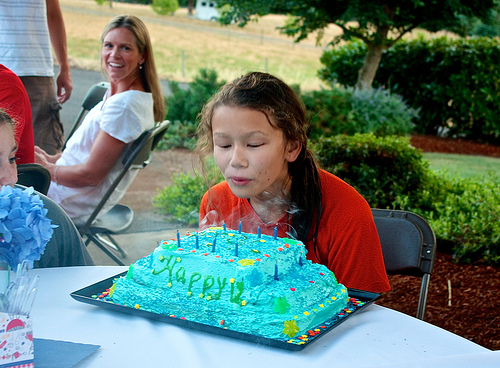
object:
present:
[0, 302, 41, 365]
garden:
[40, 0, 500, 351]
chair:
[355, 207, 435, 319]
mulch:
[380, 253, 499, 350]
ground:
[41, 110, 499, 348]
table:
[0, 264, 499, 368]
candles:
[236, 219, 243, 233]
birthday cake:
[108, 221, 350, 337]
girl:
[194, 67, 394, 300]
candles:
[222, 224, 227, 231]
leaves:
[312, 35, 325, 48]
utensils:
[0, 262, 40, 322]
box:
[0, 312, 38, 368]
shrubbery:
[314, 24, 497, 144]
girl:
[1, 109, 97, 271]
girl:
[21, 14, 163, 228]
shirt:
[46, 88, 153, 225]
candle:
[176, 231, 183, 247]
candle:
[193, 230, 200, 247]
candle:
[210, 232, 217, 251]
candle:
[232, 242, 239, 255]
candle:
[273, 260, 280, 278]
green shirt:
[9, 180, 94, 268]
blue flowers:
[1, 182, 58, 269]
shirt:
[197, 163, 390, 295]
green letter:
[149, 251, 181, 288]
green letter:
[175, 265, 186, 286]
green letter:
[187, 270, 202, 299]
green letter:
[199, 275, 215, 300]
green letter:
[216, 274, 230, 300]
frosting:
[101, 215, 353, 345]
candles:
[171, 217, 296, 278]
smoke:
[176, 188, 304, 239]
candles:
[256, 224, 262, 239]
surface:
[2, 263, 497, 368]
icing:
[112, 223, 348, 339]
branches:
[333, 22, 413, 51]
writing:
[152, 251, 246, 306]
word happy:
[152, 255, 228, 304]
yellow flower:
[279, 315, 302, 338]